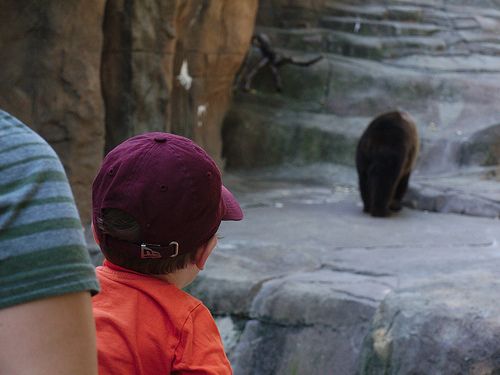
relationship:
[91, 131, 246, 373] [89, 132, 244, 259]
boy wearing hat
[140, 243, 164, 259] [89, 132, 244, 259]
logo on hat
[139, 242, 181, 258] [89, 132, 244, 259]
buckle on hat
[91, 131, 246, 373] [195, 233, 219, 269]
boy has ear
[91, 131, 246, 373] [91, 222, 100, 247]
boy has ear